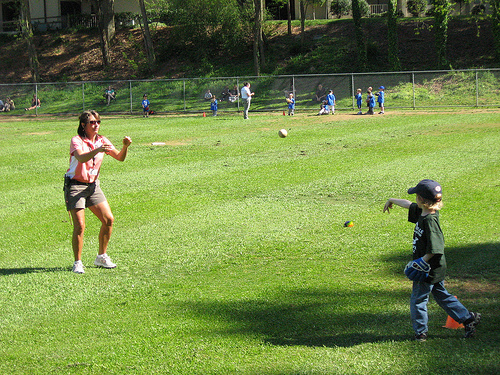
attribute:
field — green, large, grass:
[2, 112, 498, 374]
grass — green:
[1, 82, 497, 371]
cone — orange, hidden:
[446, 295, 467, 330]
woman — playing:
[64, 110, 134, 272]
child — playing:
[384, 180, 480, 339]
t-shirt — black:
[408, 200, 449, 286]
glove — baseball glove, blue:
[405, 257, 431, 286]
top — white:
[239, 87, 251, 99]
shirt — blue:
[377, 90, 386, 101]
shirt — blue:
[355, 94, 364, 104]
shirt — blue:
[210, 101, 218, 110]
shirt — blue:
[287, 96, 298, 109]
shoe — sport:
[463, 310, 480, 330]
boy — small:
[382, 178, 481, 343]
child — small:
[384, 176, 474, 352]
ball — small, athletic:
[278, 128, 291, 138]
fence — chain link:
[1, 68, 498, 115]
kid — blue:
[274, 86, 301, 118]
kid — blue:
[313, 81, 340, 115]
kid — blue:
[368, 81, 392, 115]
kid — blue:
[344, 80, 367, 115]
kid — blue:
[356, 78, 381, 121]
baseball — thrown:
[273, 126, 289, 140]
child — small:
[354, 85, 364, 112]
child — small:
[366, 87, 375, 113]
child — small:
[373, 85, 383, 115]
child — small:
[280, 93, 295, 114]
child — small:
[324, 87, 336, 113]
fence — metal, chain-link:
[1, 66, 498, 112]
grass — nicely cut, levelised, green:
[3, 115, 498, 375]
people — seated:
[1, 81, 47, 123]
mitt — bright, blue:
[404, 256, 431, 286]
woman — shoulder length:
[56, 104, 140, 284]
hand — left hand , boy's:
[382, 198, 394, 213]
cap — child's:
[407, 179, 442, 201]